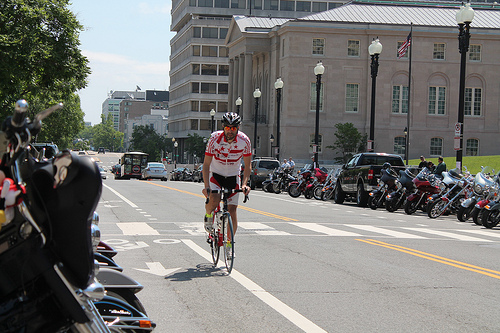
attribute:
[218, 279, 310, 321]
lines — white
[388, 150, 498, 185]
grass — green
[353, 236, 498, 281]
lines — Yellow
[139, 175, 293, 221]
lines — Yellow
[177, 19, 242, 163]
building — tall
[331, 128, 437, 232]
truck — black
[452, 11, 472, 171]
light — not lit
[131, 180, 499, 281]
line — yellow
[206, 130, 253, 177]
shirt — white, red 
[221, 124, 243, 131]
sunglasses — orange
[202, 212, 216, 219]
sock — yellow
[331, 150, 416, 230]
truck — black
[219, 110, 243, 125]
helmet — black, white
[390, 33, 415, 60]
flag — american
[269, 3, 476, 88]
globes — glass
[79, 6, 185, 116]
weather — Sunny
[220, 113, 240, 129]
helmet — black